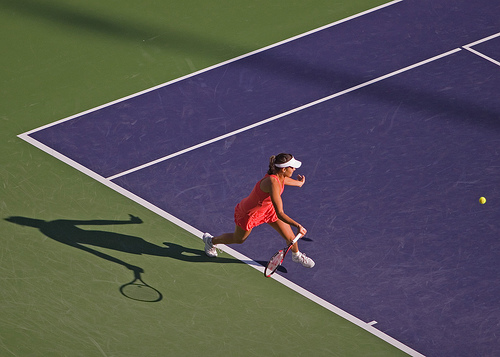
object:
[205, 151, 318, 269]
woman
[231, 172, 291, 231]
dress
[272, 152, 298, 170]
sun visor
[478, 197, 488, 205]
ball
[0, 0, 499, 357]
court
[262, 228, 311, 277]
racket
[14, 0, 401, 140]
lines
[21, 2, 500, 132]
shadow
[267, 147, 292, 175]
hair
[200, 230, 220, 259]
shoes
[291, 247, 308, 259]
socks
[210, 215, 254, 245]
leg